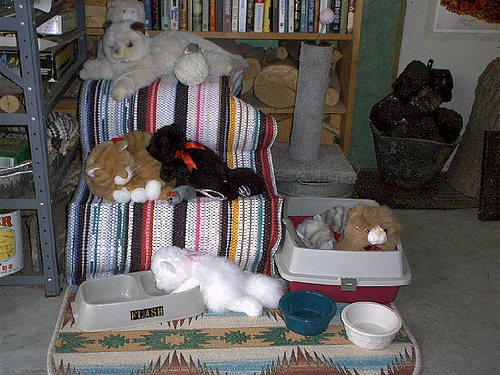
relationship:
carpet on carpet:
[289, 41, 336, 167] [289, 41, 334, 167]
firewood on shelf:
[237, 44, 347, 110] [246, 97, 345, 120]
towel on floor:
[43, 337, 421, 373] [8, 285, 496, 366]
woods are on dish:
[129, 303, 165, 323] [70, 269, 207, 334]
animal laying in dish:
[75, 20, 249, 100] [70, 269, 207, 334]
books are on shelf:
[150, 1, 356, 32] [154, 25, 359, 46]